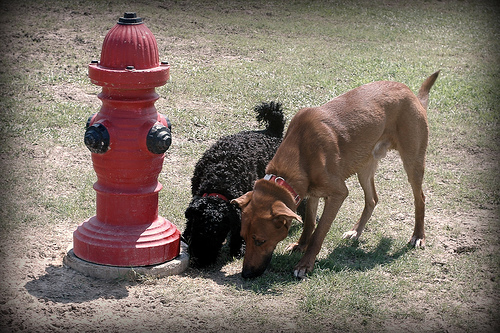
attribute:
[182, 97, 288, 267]
canine — black, small, fuzzy, curly, sniffing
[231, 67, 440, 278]
canine — brownish, medium, brown, sniffing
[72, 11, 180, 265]
hydrant — red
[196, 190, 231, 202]
collar — reddish, red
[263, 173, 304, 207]
collar — reddish, red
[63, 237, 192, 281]
base — cement, round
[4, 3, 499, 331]
earth — bare, rough, grassy, green, brown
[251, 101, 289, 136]
tail — up, black, curled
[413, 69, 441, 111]
tail — up, brown, pointy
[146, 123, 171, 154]
knob — black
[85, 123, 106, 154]
knob — black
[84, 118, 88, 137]
knob — black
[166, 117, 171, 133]
knob — black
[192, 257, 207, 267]
nose — black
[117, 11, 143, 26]
dial — black